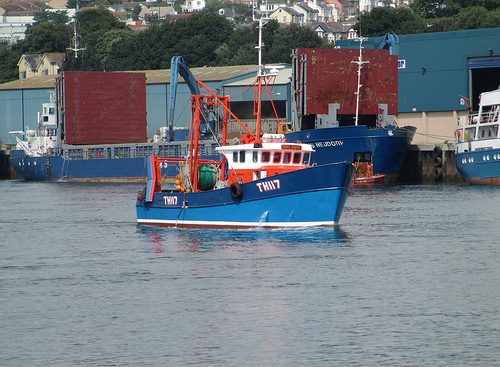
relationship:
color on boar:
[191, 216, 246, 225] [138, 216, 350, 233]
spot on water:
[108, 313, 116, 320] [4, 180, 497, 364]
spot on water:
[0, 192, 500, 367] [4, 180, 497, 364]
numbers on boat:
[256, 179, 281, 192] [134, 70, 354, 240]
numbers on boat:
[254, 177, 279, 192] [125, 143, 342, 231]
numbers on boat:
[160, 191, 177, 204] [134, 70, 354, 240]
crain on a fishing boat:
[165, 52, 217, 144] [4, 110, 415, 190]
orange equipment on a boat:
[141, 151, 218, 189] [134, 70, 354, 240]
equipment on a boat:
[139, 88, 237, 194] [112, 3, 372, 237]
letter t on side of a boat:
[251, 178, 265, 199] [135, 72, 356, 232]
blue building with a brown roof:
[3, 66, 292, 141] [0, 68, 275, 88]